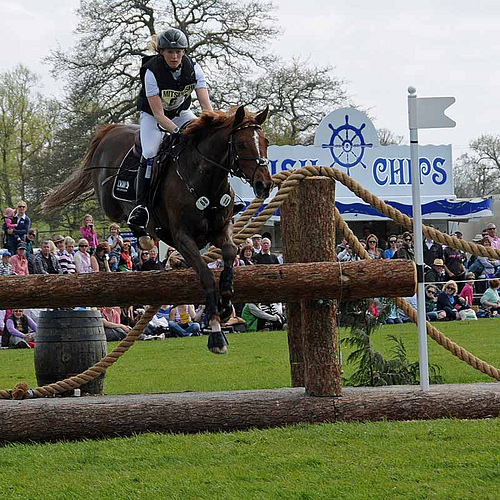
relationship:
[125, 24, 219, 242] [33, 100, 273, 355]
rider on horse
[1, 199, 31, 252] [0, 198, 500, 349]
person in crowd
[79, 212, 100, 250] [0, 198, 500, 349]
person in crowd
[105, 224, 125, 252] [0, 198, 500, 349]
person in crowd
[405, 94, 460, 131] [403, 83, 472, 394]
flag on pole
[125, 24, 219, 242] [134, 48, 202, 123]
rider wearing vest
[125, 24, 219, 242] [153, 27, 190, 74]
rider wearing helmet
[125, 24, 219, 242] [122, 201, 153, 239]
rider wearing boots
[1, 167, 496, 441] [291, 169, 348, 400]
fence has pole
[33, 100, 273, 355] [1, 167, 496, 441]
horse jumping fence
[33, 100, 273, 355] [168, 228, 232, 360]
horse has leg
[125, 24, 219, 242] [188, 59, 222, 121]
rider had arm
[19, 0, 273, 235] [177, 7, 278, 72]
tree has branch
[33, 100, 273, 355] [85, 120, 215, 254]
horse has body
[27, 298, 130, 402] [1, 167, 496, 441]
barrel behind fence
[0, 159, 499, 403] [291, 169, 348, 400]
rope on pole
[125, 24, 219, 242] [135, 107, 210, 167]
rider wearing pants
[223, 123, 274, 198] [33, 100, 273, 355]
bridle on horse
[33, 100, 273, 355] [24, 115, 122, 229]
horse has tail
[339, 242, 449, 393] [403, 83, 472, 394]
bush near pole